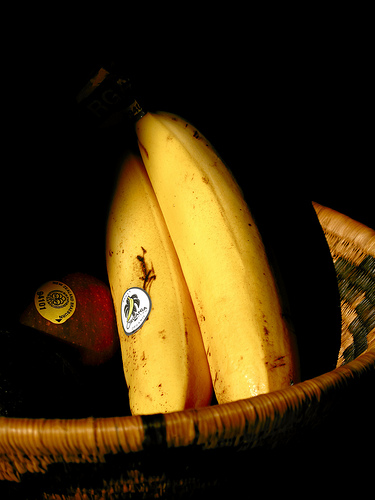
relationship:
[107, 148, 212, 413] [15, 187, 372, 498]
banana inside of basket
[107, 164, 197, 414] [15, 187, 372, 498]
banana inside of basket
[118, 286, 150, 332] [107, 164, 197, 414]
sticker on front of banana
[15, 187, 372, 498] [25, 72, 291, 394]
basket holding fruit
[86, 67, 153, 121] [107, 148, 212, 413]
stem of a banana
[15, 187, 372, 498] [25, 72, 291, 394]
basket of fruit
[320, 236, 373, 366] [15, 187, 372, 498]
markings on side of basket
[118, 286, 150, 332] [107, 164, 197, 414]
sticker with banana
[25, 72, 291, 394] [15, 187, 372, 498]
fruit inside of basket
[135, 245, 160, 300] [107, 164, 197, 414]
spots on front of banana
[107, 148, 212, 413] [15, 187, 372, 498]
banana inside of a basket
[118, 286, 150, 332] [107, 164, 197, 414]
sticker on side of banana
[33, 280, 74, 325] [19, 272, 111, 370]
sticker affixed to apple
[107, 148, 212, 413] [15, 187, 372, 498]
banana casting shadow on basket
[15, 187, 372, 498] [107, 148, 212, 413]
basket with banana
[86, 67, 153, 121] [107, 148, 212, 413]
stem of banana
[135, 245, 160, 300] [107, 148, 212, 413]
spots on side of banana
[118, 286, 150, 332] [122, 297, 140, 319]
sticker with picture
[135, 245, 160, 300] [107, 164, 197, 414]
spots on side of banana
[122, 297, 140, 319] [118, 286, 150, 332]
picture on front of sticker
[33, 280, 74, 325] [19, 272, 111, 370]
sticker on side of apple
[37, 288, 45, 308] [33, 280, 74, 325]
number on side of a sticker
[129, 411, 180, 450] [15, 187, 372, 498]
stripe on lip of basket